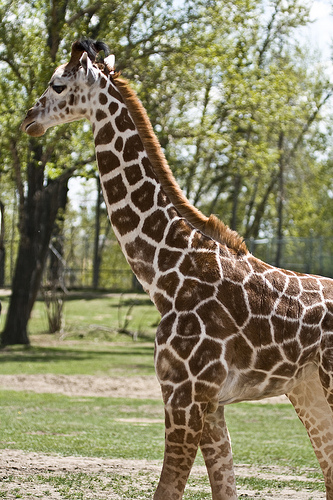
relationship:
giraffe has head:
[20, 36, 332, 499] [20, 36, 121, 139]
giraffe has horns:
[20, 36, 332, 499] [67, 38, 109, 73]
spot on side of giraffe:
[174, 277, 217, 314] [20, 36, 332, 499]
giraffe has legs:
[20, 36, 332, 499] [155, 403, 240, 499]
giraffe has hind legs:
[20, 36, 332, 499] [288, 364, 333, 499]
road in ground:
[0, 447, 328, 498] [0, 297, 332, 499]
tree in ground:
[0, 1, 323, 345] [0, 297, 332, 499]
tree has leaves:
[0, 1, 323, 345] [1, 1, 329, 179]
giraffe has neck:
[20, 36, 332, 499] [86, 110, 254, 314]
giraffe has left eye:
[20, 36, 332, 499] [51, 83, 69, 95]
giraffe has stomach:
[20, 36, 332, 499] [219, 370, 301, 406]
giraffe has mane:
[20, 36, 332, 499] [111, 69, 251, 255]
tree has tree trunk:
[0, 1, 323, 345] [0, 188, 57, 341]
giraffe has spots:
[20, 36, 332, 499] [53, 71, 332, 498]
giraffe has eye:
[20, 36, 332, 499] [51, 83, 69, 95]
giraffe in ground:
[20, 36, 332, 499] [0, 297, 332, 499]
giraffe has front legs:
[20, 36, 332, 499] [155, 403, 240, 499]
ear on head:
[79, 50, 99, 86] [20, 36, 121, 139]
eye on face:
[51, 83, 69, 95] [20, 67, 101, 138]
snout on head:
[24, 106, 38, 119] [20, 36, 121, 139]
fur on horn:
[73, 37, 97, 55] [67, 35, 96, 71]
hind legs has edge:
[288, 364, 333, 499] [285, 390, 329, 500]